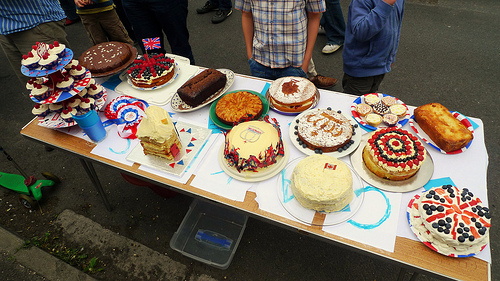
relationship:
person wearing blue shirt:
[343, 27, 403, 97] [344, 27, 399, 75]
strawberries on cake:
[424, 188, 488, 234] [418, 185, 490, 248]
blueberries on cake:
[423, 183, 491, 242] [418, 185, 490, 248]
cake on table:
[218, 112, 291, 182] [210, 50, 381, 254]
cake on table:
[291, 154, 355, 214] [210, 50, 381, 254]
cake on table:
[268, 70, 315, 108] [210, 50, 381, 254]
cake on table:
[294, 107, 359, 155] [210, 50, 381, 254]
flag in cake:
[142, 37, 162, 51] [131, 34, 180, 88]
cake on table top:
[225, 117, 286, 180] [13, 32, 484, 277]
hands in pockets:
[228, 22, 340, 83] [270, 46, 359, 91]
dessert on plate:
[171, 58, 234, 125] [159, 61, 239, 118]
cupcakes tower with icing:
[16, 32, 110, 130] [22, 33, 67, 69]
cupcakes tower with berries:
[16, 32, 110, 130] [21, 39, 71, 68]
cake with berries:
[123, 50, 183, 92] [128, 47, 173, 77]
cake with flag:
[123, 50, 183, 92] [133, 26, 168, 63]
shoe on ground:
[322, 39, 338, 55] [3, 8, 484, 278]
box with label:
[168, 198, 250, 270] [194, 226, 233, 249]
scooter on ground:
[2, 151, 55, 212] [3, 8, 484, 278]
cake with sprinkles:
[82, 41, 137, 73] [268, 77, 318, 107]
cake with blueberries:
[406, 184, 492, 260] [423, 203, 443, 215]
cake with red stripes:
[406, 184, 492, 260] [426, 210, 451, 222]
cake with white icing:
[406, 184, 492, 260] [413, 203, 463, 251]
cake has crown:
[294, 105, 354, 152] [306, 110, 345, 135]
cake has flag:
[291, 154, 355, 214] [139, 32, 169, 61]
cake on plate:
[291, 154, 355, 214] [278, 153, 365, 225]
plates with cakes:
[348, 91, 410, 131] [13, 32, 489, 244]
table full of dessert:
[19, 50, 495, 279] [177, 68, 228, 107]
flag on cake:
[143, 33, 165, 55] [122, 31, 174, 88]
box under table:
[163, 207, 248, 271] [19, 54, 493, 281]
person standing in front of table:
[341, 1, 411, 103] [19, 50, 495, 279]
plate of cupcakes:
[345, 80, 415, 130] [348, 91, 410, 131]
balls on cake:
[431, 206, 482, 243] [406, 168, 496, 261]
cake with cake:
[295, 152, 355, 214] [409, 178, 499, 256]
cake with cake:
[294, 107, 359, 155] [409, 178, 499, 256]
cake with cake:
[363, 118, 432, 205] [409, 178, 499, 256]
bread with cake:
[414, 102, 473, 153] [409, 178, 499, 256]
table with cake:
[19, 54, 493, 281] [409, 178, 499, 256]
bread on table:
[413, 102, 470, 149] [19, 50, 495, 279]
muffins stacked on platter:
[32, 43, 88, 98] [20, 38, 107, 130]